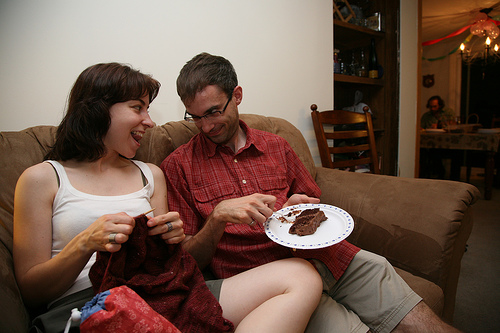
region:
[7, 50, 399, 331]
man and woman sitting on a sofa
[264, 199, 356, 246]
the white plate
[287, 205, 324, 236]
the food on the plate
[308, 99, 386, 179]
the backing of a wooden chair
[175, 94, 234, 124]
glasses on the man's face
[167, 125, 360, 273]
the buttoned up shirt on the man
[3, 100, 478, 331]
the brown sofa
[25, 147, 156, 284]
the woman's white tank top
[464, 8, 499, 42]
the balloons hanging from a light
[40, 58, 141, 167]
the hair on the woman's head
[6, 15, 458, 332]
2 people on the couch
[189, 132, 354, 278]
man is holding a plate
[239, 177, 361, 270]
the plate is white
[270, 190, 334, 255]
cake is on the plate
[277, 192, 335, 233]
the cake is chocolate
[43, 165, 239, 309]
the woman is crocheting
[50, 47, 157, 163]
the woman is smiling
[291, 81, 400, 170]
the chair is brown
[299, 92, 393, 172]
the chair is made of wood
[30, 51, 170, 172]
the woman`s hair is brown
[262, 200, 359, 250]
A piece of cake on a plate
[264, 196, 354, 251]
Desert on a plate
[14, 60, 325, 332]
Woman doing some knitting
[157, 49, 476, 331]
Man looking at the woman knitting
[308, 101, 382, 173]
Back of a wooden chair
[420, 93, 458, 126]
Man sitting in the adjoining room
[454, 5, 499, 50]
Light attached to the ceiling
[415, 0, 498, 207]
Doorway to the adjoining room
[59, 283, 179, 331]
Bag containing a ball of yarn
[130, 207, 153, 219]
Needle used to knit or crochet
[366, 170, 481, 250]
arm of a sofa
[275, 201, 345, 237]
piece of chocolate cake on a plate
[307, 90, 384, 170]
back of a chair against the wall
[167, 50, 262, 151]
man with glasses on looking down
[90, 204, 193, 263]
hands with knitting needle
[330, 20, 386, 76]
bottles on a shelf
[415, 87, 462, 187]
man sitting at a table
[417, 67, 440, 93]
plaque hanging on a wall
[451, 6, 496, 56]
chandelier attached to the ceiling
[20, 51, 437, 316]
man and woman seated on a couch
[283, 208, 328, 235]
piece of chocolate cake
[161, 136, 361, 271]
red shirt with white buttons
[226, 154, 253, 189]
white buttons on red shirt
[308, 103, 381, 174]
back of brown wooden chair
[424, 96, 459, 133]
man sitting at table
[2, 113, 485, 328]
tan fabric couch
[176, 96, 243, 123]
glasses on mans face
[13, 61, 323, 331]
woman wearing white tank top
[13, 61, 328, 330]
woman crocheting a blanket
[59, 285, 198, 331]
red and blue bag of yarn